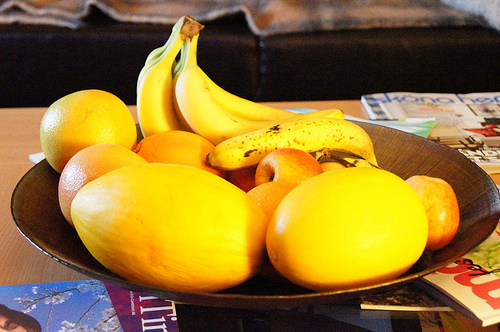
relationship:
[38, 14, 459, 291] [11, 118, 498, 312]
fruit inside of bowl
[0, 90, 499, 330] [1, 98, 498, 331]
magazines on top of table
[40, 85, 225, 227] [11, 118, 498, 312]
oranges inside of bowl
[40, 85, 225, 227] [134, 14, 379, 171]
oranges next to bananas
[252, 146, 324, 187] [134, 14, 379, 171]
apple in middle of bananas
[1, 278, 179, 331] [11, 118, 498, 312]
magazine underneath bowl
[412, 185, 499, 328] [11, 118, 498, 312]
magazine underneath bowl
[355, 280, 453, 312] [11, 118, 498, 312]
magazine underneath bowl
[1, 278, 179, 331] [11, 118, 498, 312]
magazine on left side of bowl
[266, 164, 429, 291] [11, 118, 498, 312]
mango inside of bowl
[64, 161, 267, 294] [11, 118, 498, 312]
mango inside of bowl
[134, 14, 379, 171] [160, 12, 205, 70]
bananas have stem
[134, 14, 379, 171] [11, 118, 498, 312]
bananas inside of bowl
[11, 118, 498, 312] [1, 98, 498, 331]
bowl on top of table